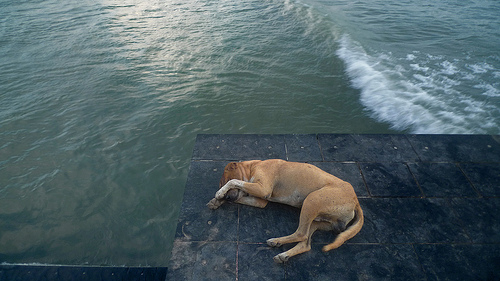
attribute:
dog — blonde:
[200, 160, 367, 262]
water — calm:
[8, 108, 165, 255]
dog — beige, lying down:
[207, 154, 378, 261]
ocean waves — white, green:
[315, 31, 400, 123]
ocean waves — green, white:
[315, 19, 424, 121]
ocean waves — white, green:
[413, 49, 484, 110]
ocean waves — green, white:
[245, 38, 307, 102]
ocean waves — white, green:
[77, 29, 129, 109]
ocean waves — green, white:
[195, 34, 245, 101]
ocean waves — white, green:
[76, 66, 158, 137]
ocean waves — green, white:
[91, 139, 130, 187]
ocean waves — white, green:
[39, 170, 99, 230]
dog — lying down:
[209, 141, 366, 262]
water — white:
[329, 29, 460, 135]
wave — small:
[318, 15, 418, 126]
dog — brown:
[203, 153, 365, 265]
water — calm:
[4, 6, 495, 266]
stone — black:
[173, 128, 494, 276]